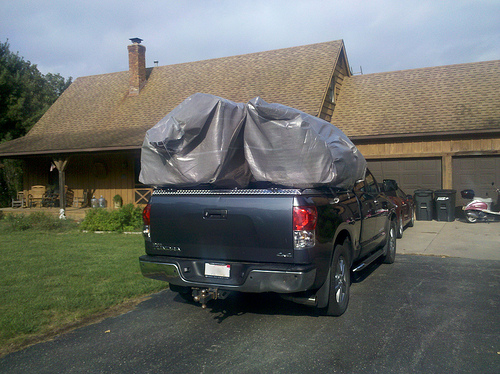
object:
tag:
[204, 262, 231, 278]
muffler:
[283, 295, 317, 306]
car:
[375, 182, 416, 238]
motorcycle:
[459, 188, 500, 224]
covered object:
[138, 91, 369, 188]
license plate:
[205, 262, 231, 278]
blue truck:
[137, 92, 399, 316]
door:
[453, 154, 500, 216]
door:
[368, 158, 442, 198]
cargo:
[137, 93, 369, 189]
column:
[453, 156, 500, 203]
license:
[205, 262, 232, 277]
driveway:
[0, 228, 499, 374]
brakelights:
[291, 204, 318, 249]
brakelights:
[141, 200, 151, 242]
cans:
[433, 189, 456, 222]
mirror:
[383, 179, 399, 190]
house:
[3, 35, 498, 230]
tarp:
[135, 92, 372, 189]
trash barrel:
[413, 189, 434, 221]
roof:
[0, 39, 353, 157]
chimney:
[128, 37, 145, 92]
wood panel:
[68, 159, 130, 204]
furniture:
[136, 91, 370, 191]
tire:
[321, 243, 352, 317]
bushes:
[77, 204, 141, 231]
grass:
[14, 229, 124, 304]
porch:
[0, 160, 146, 223]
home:
[2, 36, 500, 219]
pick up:
[134, 161, 371, 317]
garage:
[335, 60, 497, 220]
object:
[139, 91, 368, 191]